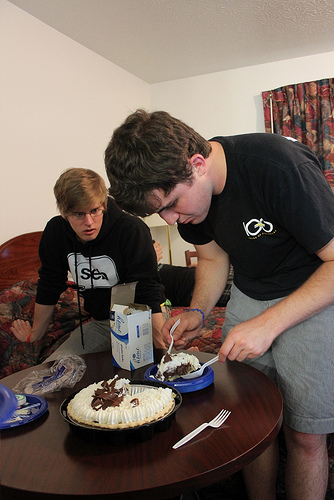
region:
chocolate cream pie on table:
[61, 374, 181, 430]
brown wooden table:
[0, 332, 293, 499]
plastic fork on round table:
[171, 407, 238, 447]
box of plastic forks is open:
[109, 277, 154, 373]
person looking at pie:
[12, 166, 176, 361]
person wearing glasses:
[67, 206, 102, 222]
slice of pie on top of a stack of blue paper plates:
[143, 352, 213, 390]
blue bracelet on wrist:
[182, 304, 210, 327]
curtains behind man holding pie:
[260, 76, 332, 190]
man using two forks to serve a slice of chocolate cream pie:
[106, 109, 333, 497]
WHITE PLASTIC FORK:
[167, 407, 232, 450]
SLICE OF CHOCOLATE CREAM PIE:
[149, 350, 202, 386]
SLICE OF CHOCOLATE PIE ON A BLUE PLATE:
[143, 352, 215, 393]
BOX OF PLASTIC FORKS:
[103, 299, 163, 372]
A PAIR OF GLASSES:
[64, 206, 105, 222]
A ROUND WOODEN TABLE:
[3, 338, 295, 494]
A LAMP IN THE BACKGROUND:
[135, 204, 187, 267]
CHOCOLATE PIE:
[53, 372, 186, 440]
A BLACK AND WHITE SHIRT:
[30, 213, 183, 317]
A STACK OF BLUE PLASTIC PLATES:
[139, 362, 221, 394]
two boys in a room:
[2, 124, 332, 431]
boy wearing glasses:
[0, 156, 172, 368]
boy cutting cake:
[93, 79, 333, 452]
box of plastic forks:
[90, 282, 169, 382]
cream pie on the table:
[58, 363, 191, 441]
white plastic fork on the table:
[158, 400, 247, 456]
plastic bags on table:
[11, 346, 88, 403]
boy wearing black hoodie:
[17, 153, 178, 343]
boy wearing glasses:
[63, 192, 110, 227]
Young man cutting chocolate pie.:
[101, 109, 326, 419]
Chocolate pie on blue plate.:
[151, 352, 204, 381]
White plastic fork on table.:
[166, 405, 231, 453]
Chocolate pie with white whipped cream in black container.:
[58, 378, 183, 441]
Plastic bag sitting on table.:
[18, 350, 89, 397]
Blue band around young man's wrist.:
[182, 306, 213, 332]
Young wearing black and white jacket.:
[32, 202, 180, 319]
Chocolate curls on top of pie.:
[93, 384, 126, 411]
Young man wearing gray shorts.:
[222, 283, 333, 454]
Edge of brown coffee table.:
[13, 426, 286, 486]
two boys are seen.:
[53, 134, 314, 260]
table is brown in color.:
[45, 446, 141, 487]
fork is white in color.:
[174, 407, 227, 448]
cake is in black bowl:
[69, 376, 169, 444]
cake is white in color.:
[79, 380, 168, 443]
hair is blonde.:
[61, 180, 104, 202]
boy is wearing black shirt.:
[227, 215, 304, 256]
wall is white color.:
[31, 78, 79, 113]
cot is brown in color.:
[0, 234, 44, 266]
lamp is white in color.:
[151, 215, 167, 233]